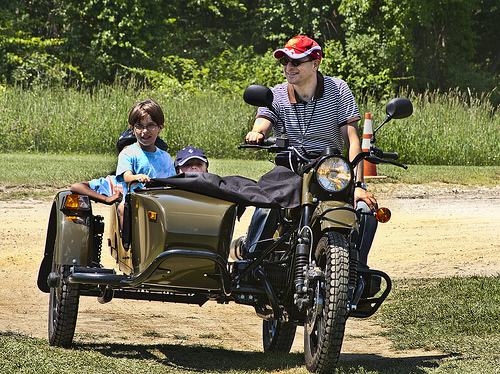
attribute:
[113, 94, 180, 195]
boy — sitting, young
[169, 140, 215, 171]
cap — blue, red yellow, white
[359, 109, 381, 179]
cone — orange, white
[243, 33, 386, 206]
man — smiling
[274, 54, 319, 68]
sunglasses — black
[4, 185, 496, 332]
road — dirt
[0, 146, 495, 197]
grass — tall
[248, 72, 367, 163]
shirt — polo, black, white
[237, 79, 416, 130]
mirrors — black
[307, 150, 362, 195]
headlight — orange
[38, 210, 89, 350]
wheel — skinny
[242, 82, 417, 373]
motorcycle — brown, gold